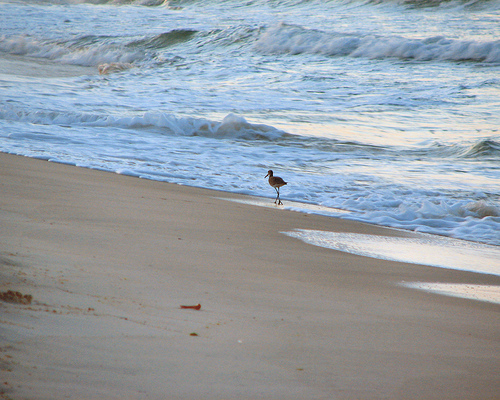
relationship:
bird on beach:
[264, 170, 288, 205] [259, 165, 289, 205]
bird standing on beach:
[264, 170, 288, 205] [21, 36, 499, 377]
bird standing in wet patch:
[264, 170, 288, 205] [248, 192, 332, 221]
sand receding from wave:
[339, 236, 394, 252] [122, 108, 495, 160]